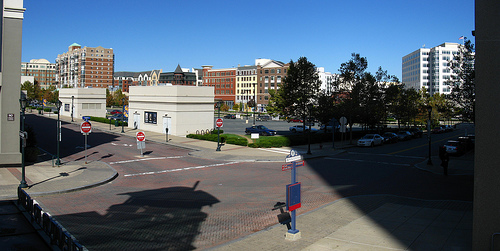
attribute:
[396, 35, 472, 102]
building — tall, white, highrise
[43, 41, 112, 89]
building — tall, highrise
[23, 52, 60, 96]
building — tall, highrise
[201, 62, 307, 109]
building — tall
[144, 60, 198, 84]
building — tall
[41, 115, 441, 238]
street — brick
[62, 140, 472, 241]
brick — red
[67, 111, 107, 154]
sign — do-not-enter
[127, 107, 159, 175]
street sign — says do not enter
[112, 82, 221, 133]
building — square, plain, gray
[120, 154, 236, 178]
lines — white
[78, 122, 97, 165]
sign — red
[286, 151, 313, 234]
pole — blue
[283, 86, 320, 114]
leaves — green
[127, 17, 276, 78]
sky — clear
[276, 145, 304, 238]
pole — blue, red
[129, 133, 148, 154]
sign — red, white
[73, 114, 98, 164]
sign — red, white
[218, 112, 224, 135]
sign — red, white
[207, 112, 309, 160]
car — White 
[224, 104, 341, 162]
car — White 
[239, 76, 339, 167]
sign — White 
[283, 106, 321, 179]
pole — blue 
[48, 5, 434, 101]
sky — blue , Bright 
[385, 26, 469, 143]
building — tall , white 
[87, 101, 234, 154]
signs — Red 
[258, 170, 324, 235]
pole — blue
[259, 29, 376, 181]
building — white 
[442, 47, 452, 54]
window — glass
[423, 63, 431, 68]
window — glass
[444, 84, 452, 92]
window — glass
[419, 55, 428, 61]
window — glass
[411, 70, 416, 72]
window — glass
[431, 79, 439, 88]
window — glass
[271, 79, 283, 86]
window — glass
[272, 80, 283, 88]
window — glass